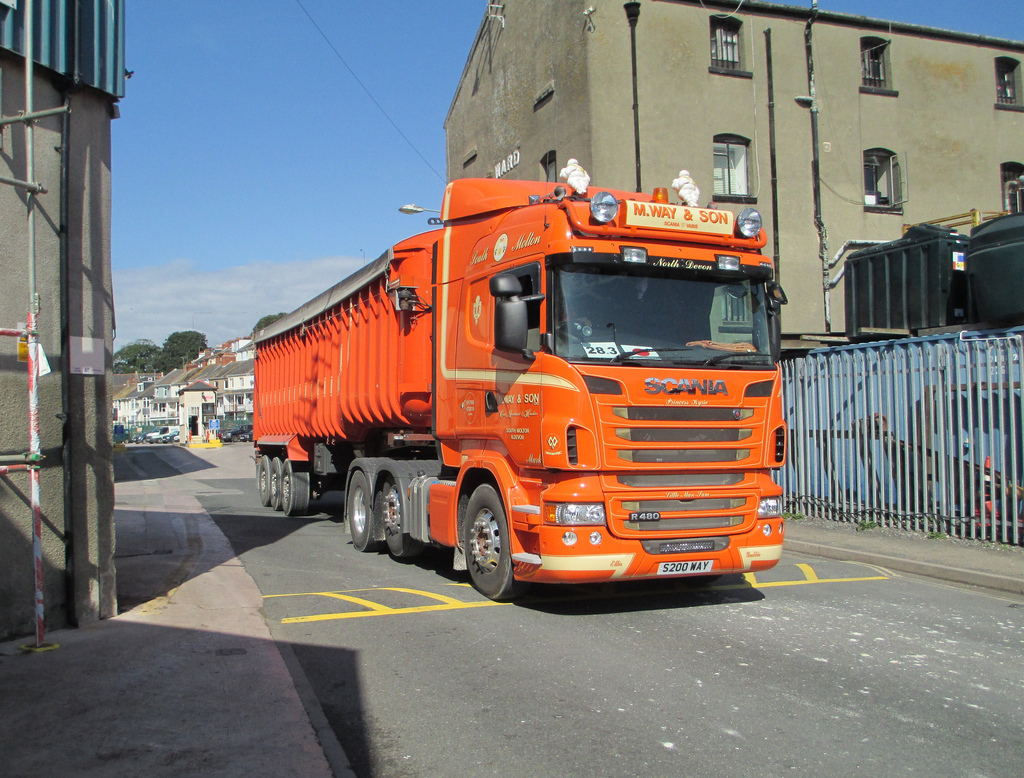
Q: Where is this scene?
A: On the street.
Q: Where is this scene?
A: On a street.